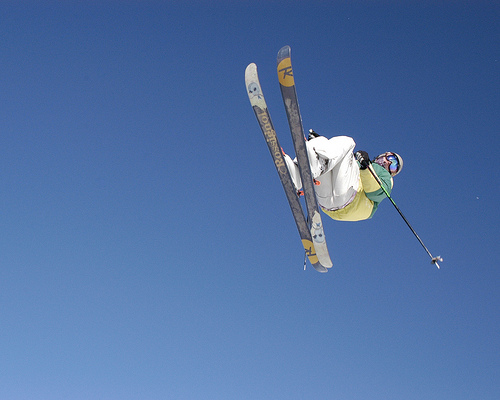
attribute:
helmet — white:
[360, 136, 440, 185]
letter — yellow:
[280, 61, 293, 85]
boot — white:
[279, 144, 304, 195]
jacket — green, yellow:
[334, 166, 384, 225]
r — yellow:
[295, 235, 322, 272]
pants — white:
[294, 132, 362, 212]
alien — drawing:
[242, 78, 268, 110]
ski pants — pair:
[274, 134, 359, 211]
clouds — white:
[44, 28, 166, 138]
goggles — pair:
[385, 152, 400, 174]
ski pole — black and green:
[356, 152, 443, 271]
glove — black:
[354, 148, 368, 166]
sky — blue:
[47, 107, 139, 204]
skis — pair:
[214, 45, 336, 293]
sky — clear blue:
[3, 4, 238, 373]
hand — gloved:
[353, 147, 373, 169]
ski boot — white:
[277, 136, 334, 195]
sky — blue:
[14, 4, 499, 399]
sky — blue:
[79, 135, 269, 312]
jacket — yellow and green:
[333, 163, 391, 220]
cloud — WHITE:
[12, 228, 152, 390]